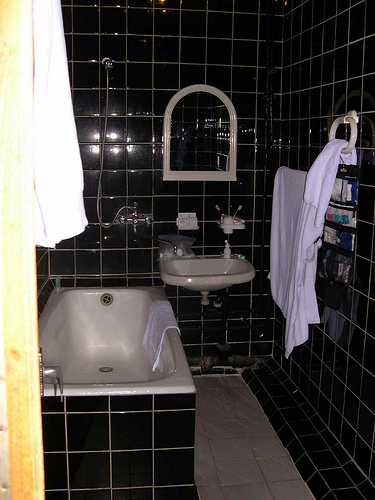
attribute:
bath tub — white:
[35, 277, 191, 398]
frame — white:
[160, 83, 237, 181]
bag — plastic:
[154, 232, 199, 259]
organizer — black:
[309, 150, 365, 315]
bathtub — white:
[24, 276, 204, 494]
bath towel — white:
[265, 157, 324, 346]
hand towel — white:
[301, 139, 364, 225]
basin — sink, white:
[187, 256, 247, 297]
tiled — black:
[62, 3, 157, 282]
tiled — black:
[181, 5, 374, 84]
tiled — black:
[237, 91, 272, 336]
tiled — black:
[278, 316, 371, 497]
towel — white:
[267, 165, 324, 358]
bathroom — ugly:
[0, 5, 362, 493]